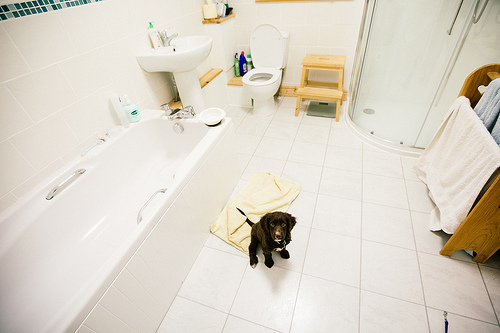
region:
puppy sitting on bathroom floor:
[228, 198, 304, 275]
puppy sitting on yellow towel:
[228, 194, 312, 276]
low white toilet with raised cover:
[243, 25, 300, 126]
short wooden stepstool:
[288, 43, 356, 126]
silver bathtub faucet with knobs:
[155, 101, 196, 136]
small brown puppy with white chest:
[231, 201, 308, 275]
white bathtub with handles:
[0, 86, 242, 331]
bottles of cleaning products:
[231, 48, 252, 75]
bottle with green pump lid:
[139, 15, 167, 49]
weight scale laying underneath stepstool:
[304, 94, 338, 119]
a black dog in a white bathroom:
[224, 198, 326, 280]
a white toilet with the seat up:
[227, 26, 286, 123]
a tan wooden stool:
[284, 47, 357, 134]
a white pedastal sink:
[129, 20, 232, 139]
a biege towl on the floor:
[205, 165, 279, 253]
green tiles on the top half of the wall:
[0, 5, 76, 22]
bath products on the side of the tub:
[93, 89, 153, 138]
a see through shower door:
[341, 1, 466, 183]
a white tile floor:
[311, 170, 433, 315]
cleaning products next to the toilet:
[230, 51, 252, 81]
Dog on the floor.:
[228, 205, 308, 267]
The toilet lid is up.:
[230, 29, 290, 111]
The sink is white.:
[135, 22, 222, 114]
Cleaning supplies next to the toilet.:
[223, 43, 253, 82]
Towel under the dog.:
[225, 170, 295, 245]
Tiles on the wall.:
[15, 24, 100, 139]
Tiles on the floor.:
[340, 181, 427, 323]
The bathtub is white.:
[26, 128, 207, 293]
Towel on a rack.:
[428, 110, 488, 212]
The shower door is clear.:
[358, 2, 445, 150]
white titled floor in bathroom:
[309, 148, 414, 331]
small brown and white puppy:
[237, 207, 295, 282]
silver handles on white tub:
[5, 119, 188, 324]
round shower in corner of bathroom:
[351, 2, 496, 147]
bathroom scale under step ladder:
[290, 57, 347, 126]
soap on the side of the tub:
[110, 90, 142, 128]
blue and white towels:
[414, 68, 497, 229]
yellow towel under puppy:
[207, 168, 308, 274]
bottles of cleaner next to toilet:
[230, 43, 284, 101]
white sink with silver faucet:
[139, 19, 213, 111]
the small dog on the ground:
[235, 205, 295, 268]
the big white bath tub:
[9, 104, 231, 331]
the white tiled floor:
[309, 158, 420, 328]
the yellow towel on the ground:
[223, 162, 291, 271]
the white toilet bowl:
[237, 22, 288, 118]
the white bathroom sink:
[140, 23, 210, 123]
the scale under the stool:
[307, 95, 337, 119]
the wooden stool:
[297, 52, 344, 123]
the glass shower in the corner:
[347, 2, 499, 145]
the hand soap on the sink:
[145, 16, 162, 48]